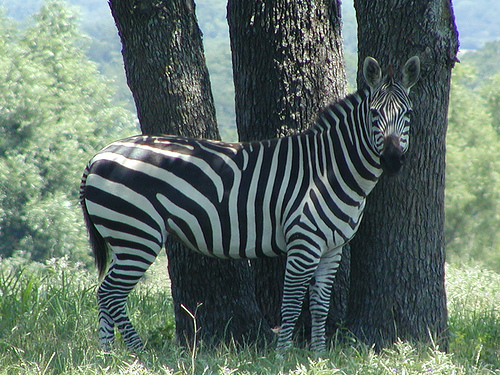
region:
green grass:
[50, 274, 92, 345]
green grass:
[38, 242, 103, 344]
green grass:
[18, 282, 73, 343]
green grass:
[451, 318, 496, 373]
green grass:
[447, 292, 494, 330]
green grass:
[464, 310, 494, 330]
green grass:
[472, 308, 494, 368]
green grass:
[451, 314, 481, 336]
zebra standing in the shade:
[60, 51, 435, 361]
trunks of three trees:
[100, 0, 465, 52]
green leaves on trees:
[5, 12, 75, 292]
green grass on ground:
[11, 350, 256, 370]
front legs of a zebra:
[265, 255, 335, 355]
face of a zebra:
[347, 40, 432, 180]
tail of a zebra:
[75, 152, 105, 277]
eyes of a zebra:
[365, 100, 415, 120]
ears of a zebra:
[355, 55, 425, 85]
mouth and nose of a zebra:
[368, 132, 413, 177]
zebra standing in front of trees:
[72, 88, 446, 343]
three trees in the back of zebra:
[75, 19, 451, 57]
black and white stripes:
[121, 120, 358, 332]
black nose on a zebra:
[371, 131, 425, 200]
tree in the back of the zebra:
[14, 31, 140, 186]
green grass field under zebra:
[452, 296, 489, 373]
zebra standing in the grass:
[46, 74, 387, 374]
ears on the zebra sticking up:
[311, 31, 455, 108]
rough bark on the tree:
[248, 34, 306, 89]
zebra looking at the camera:
[28, 48, 468, 374]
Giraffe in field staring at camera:
[104, 63, 417, 358]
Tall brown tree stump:
[117, 7, 230, 354]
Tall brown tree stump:
[232, 20, 349, 330]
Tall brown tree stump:
[347, 18, 452, 336]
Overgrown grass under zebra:
[37, 291, 499, 366]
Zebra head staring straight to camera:
[366, 63, 428, 168]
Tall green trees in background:
[10, 28, 116, 233]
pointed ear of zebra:
[358, 52, 382, 87]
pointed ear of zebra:
[401, 49, 417, 92]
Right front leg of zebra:
[281, 241, 302, 353]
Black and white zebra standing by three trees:
[77, 54, 421, 361]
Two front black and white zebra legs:
[275, 232, 343, 364]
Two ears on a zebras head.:
[362, 54, 422, 93]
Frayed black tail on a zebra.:
[84, 222, 106, 280]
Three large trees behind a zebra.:
[106, 0, 461, 347]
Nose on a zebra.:
[378, 149, 405, 174]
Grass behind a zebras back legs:
[3, 265, 170, 370]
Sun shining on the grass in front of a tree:
[382, 340, 460, 373]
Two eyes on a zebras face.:
[368, 105, 412, 116]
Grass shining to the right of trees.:
[446, 258, 498, 310]